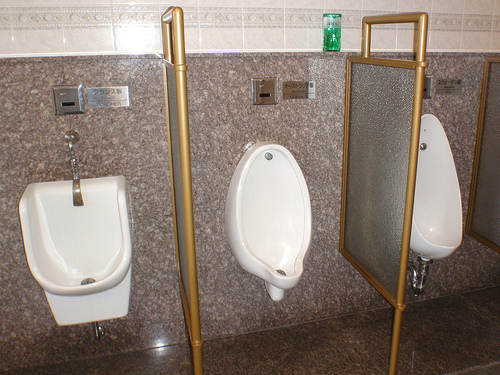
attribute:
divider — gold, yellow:
[159, 6, 208, 374]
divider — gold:
[337, 10, 431, 374]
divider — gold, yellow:
[464, 54, 500, 258]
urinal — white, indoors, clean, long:
[408, 113, 466, 268]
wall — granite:
[2, 2, 499, 372]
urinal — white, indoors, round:
[222, 139, 316, 305]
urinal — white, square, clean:
[15, 172, 138, 332]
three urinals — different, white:
[17, 110, 468, 327]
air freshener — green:
[320, 11, 344, 55]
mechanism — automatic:
[48, 81, 88, 119]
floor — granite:
[2, 282, 499, 374]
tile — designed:
[1, 1, 498, 54]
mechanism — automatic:
[252, 74, 281, 107]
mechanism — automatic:
[421, 72, 436, 100]